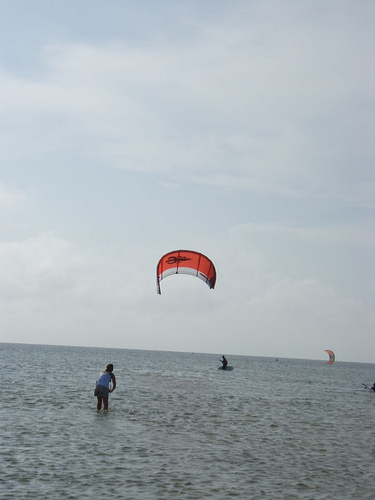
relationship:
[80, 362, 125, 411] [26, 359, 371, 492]
woman in lake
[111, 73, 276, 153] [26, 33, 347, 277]
clouds in sky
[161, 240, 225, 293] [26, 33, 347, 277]
kite in sky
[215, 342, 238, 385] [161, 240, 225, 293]
person flying kite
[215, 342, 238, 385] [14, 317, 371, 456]
person in ocean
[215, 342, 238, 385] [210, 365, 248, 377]
person on surfboard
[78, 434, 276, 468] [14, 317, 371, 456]
ripple in ocean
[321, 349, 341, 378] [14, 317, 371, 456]
sail in ocean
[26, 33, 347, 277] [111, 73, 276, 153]
sky has clouds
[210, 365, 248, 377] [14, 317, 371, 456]
surfboard in ocean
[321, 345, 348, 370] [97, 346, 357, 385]
parasail in water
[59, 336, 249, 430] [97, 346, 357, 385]
people standing in water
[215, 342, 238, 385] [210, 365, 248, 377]
person carrying surfboard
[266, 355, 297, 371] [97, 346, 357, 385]
person in water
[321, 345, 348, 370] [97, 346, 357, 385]
parasail near water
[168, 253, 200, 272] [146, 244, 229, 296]
design on parasail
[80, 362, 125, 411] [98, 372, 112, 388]
woman wearing top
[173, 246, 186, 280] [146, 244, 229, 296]
rod in parasail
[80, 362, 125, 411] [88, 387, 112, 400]
woman wearing shorts